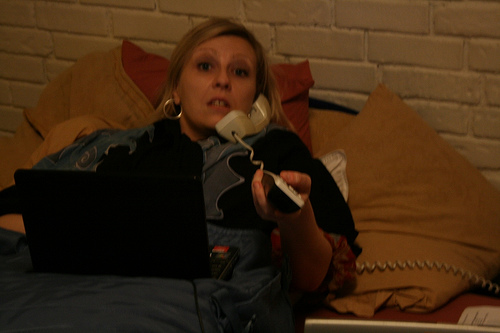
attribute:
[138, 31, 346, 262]
woman — is brown, laying, looking, close, here, young, blonde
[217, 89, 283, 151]
phone — old, here, close, white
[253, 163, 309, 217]
remote — is white, here, is black, is gray, black, white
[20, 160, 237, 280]
computer — large, black, is black, here, open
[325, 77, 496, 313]
case — is golden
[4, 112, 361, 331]
shirt — blue, is gray, is black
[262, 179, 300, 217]
bottom — is black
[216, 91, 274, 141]
phone — is white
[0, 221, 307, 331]
blanket — is blue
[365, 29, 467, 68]
brick — is white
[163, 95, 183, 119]
hoop earring — is silver